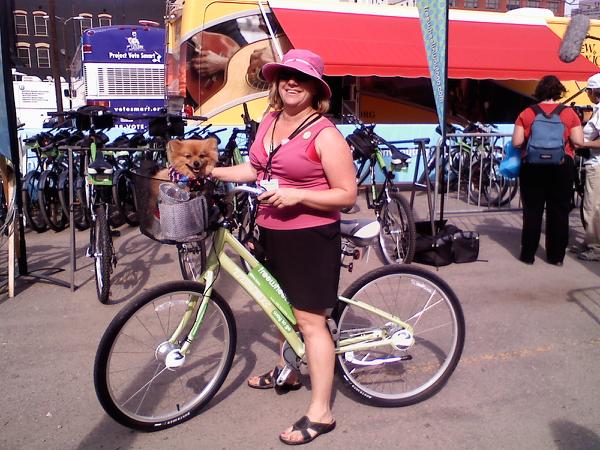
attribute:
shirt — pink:
[248, 104, 341, 230]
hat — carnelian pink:
[259, 46, 334, 102]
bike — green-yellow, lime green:
[91, 159, 467, 433]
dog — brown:
[142, 134, 220, 209]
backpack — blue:
[520, 101, 568, 169]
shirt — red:
[513, 98, 581, 157]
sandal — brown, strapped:
[276, 413, 339, 447]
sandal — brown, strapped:
[248, 367, 302, 391]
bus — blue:
[59, 25, 166, 132]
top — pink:
[246, 107, 345, 231]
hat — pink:
[257, 45, 333, 99]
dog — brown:
[148, 136, 220, 210]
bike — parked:
[18, 107, 60, 231]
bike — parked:
[34, 111, 71, 233]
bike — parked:
[55, 106, 88, 230]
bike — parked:
[129, 107, 204, 223]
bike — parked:
[118, 109, 145, 225]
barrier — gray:
[433, 130, 578, 223]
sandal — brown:
[258, 379, 411, 447]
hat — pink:
[244, 27, 360, 124]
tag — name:
[235, 169, 309, 221]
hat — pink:
[243, 32, 381, 124]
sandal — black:
[276, 403, 316, 441]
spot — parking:
[48, 283, 571, 447]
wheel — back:
[332, 244, 504, 425]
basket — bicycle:
[109, 189, 223, 242]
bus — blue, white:
[44, 28, 168, 130]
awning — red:
[264, 10, 580, 129]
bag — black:
[338, 118, 384, 193]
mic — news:
[538, 9, 581, 72]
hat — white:
[576, 62, 582, 83]